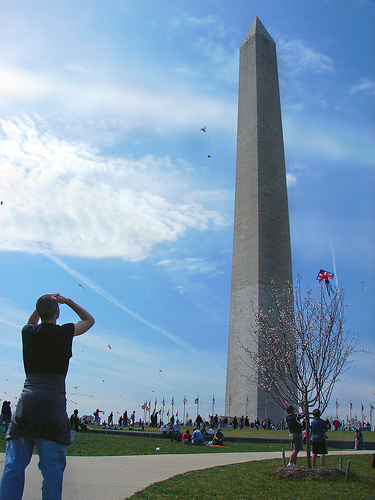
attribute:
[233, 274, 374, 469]
tree — bare, flowering, budding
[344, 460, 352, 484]
pole — gray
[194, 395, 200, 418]
flag pole — tall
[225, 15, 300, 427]
monument — tall, gray, washington, large, cement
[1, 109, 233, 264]
clouds — white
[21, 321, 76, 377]
shirt — black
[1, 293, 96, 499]
man — looking up, covering eyes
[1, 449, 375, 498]
walkway — gray, concrete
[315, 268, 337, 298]
kite — colorful, red, blue, white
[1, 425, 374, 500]
grass — green, trimmed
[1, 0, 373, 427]
sky — blue, clear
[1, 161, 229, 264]
cloud — large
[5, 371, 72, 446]
sweatshirt — gray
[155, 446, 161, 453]
object — white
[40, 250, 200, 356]
streak — white